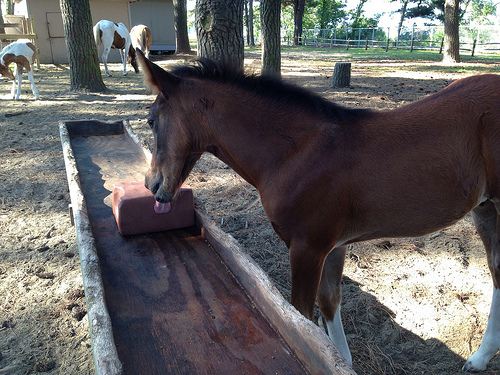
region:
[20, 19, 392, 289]
this is on a farm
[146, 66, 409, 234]
this is a horse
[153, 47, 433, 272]
this is a small horse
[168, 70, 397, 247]
the horse is brown and white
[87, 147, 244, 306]
the horse has its tongue out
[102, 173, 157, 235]
this is a salt lick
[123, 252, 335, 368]
this is a trough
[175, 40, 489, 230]
this is a horse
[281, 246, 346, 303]
these are the legs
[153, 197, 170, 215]
this is the tongue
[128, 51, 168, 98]
this is the ear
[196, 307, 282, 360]
this is a basin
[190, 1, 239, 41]
this is a tree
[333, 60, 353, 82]
the tree is cut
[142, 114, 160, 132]
this is the eye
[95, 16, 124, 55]
the horse is white in color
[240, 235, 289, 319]
edge of a wood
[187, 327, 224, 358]
part iof a wood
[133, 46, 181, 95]
ear of a horse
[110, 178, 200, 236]
a brown salt brick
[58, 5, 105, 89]
the trunk of a tree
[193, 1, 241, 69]
the trunk of a tree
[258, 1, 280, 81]
the trunk of a tree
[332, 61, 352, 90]
the stump of a tree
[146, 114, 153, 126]
eye of a horse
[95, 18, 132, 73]
a horse is brown and white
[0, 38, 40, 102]
a horse is brown and white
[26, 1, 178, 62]
a tan colored building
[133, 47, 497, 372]
the brown and white horse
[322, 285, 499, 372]
the white on the horse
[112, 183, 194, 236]
the horse lick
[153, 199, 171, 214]
the tongue from the horse's mouth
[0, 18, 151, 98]
the horses in the background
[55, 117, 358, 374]
the trough in front of the horse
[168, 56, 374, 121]
the mane on the horse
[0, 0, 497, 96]
the trees around the horses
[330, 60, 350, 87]
the short tree stump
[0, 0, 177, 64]
the building near the horses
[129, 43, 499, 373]
a standing brown pony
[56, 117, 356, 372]
a wooden trough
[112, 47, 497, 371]
a pony licking a block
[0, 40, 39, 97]
a brown and white standing horse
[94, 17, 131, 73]
a brown and white standing horse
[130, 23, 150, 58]
a brown and white standing horse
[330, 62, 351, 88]
a tree stump in distance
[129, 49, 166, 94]
ear of the horse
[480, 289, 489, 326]
dirt on the ground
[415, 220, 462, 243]
stomach of the horse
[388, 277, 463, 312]
sunlight on the dirt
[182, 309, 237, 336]
water in the trough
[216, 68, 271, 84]
mane of the horse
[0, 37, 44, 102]
the horse is standing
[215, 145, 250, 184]
neck of the horse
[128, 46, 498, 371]
horse drinking water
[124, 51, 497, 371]
brown horse with white legs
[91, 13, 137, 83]
brown and white horse is eating grass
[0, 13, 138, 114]
two white horses with brown spots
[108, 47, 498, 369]
brown horse licking the sponge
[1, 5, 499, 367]
four horses in the field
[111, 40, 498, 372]
young brown horse